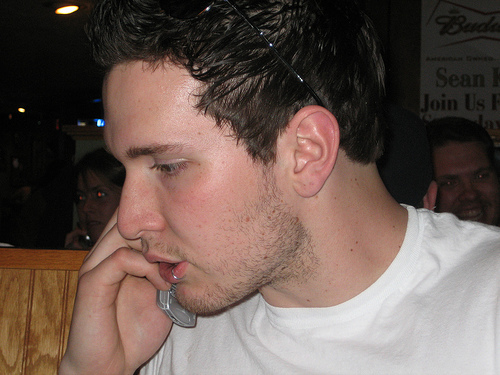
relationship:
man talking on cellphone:
[53, 0, 497, 375] [153, 287, 200, 329]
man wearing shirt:
[53, 0, 497, 375] [124, 200, 498, 374]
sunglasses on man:
[219, 2, 329, 109] [53, 0, 497, 375]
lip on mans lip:
[170, 265, 189, 280] [156, 263, 190, 281]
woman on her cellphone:
[60, 154, 134, 255] [81, 226, 96, 246]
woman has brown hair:
[60, 154, 134, 255] [69, 140, 132, 197]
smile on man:
[457, 205, 493, 222] [426, 114, 500, 230]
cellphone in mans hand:
[153, 287, 200, 329] [68, 208, 182, 374]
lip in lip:
[170, 265, 189, 280] [156, 263, 190, 281]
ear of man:
[284, 103, 344, 200] [53, 0, 497, 375]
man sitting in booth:
[53, 0, 497, 375] [3, 249, 105, 373]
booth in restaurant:
[3, 249, 105, 373] [1, 0, 497, 373]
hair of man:
[80, 1, 393, 169] [53, 0, 497, 375]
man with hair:
[426, 114, 500, 230] [426, 115, 500, 171]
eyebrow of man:
[127, 143, 199, 156] [53, 0, 497, 375]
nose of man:
[115, 169, 166, 240] [53, 0, 497, 375]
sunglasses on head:
[219, 2, 329, 109] [97, 7, 389, 320]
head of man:
[97, 7, 389, 320] [53, 0, 497, 375]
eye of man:
[148, 156, 196, 175] [53, 0, 497, 375]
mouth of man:
[142, 253, 196, 287] [53, 0, 497, 375]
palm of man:
[111, 277, 176, 363] [53, 0, 497, 375]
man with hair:
[53, 0, 497, 375] [80, 1, 393, 169]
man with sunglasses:
[53, 0, 497, 375] [219, 2, 329, 109]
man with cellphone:
[53, 0, 497, 375] [153, 287, 200, 329]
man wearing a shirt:
[53, 0, 497, 375] [124, 200, 498, 374]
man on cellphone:
[53, 0, 497, 375] [153, 287, 200, 329]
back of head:
[311, 1, 396, 158] [97, 7, 389, 320]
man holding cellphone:
[53, 0, 497, 375] [153, 287, 200, 329]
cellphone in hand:
[153, 287, 200, 329] [68, 208, 182, 374]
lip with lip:
[156, 263, 190, 281] [170, 265, 189, 280]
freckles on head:
[236, 206, 282, 226] [97, 7, 389, 320]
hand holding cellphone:
[68, 208, 182, 374] [153, 287, 200, 329]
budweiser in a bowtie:
[423, 1, 500, 54] [423, 1, 500, 56]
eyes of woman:
[72, 183, 114, 210] [60, 154, 134, 255]